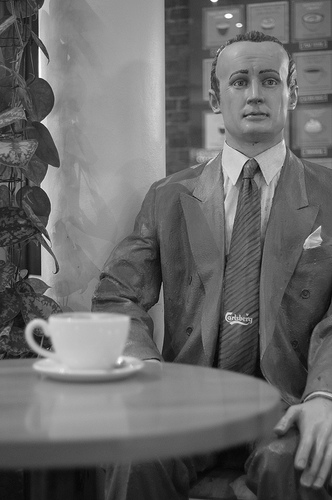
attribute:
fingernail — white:
[295, 457, 304, 467]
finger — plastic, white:
[295, 431, 309, 472]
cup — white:
[42, 314, 131, 386]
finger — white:
[300, 436, 320, 489]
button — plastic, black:
[185, 273, 192, 283]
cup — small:
[27, 307, 132, 364]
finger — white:
[272, 402, 299, 436]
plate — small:
[39, 352, 154, 377]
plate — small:
[31, 352, 143, 380]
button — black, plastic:
[297, 286, 311, 301]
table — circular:
[1, 358, 283, 468]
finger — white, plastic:
[293, 421, 314, 473]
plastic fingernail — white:
[293, 456, 328, 491]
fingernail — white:
[272, 423, 281, 433]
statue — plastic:
[82, 35, 330, 497]